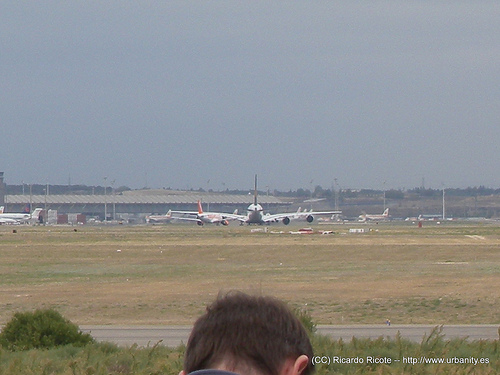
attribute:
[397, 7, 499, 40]
clouds — white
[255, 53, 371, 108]
clouds — white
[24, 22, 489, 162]
sky — blue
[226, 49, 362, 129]
sky — blue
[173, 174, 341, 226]
plane — white 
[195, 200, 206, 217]
tail — red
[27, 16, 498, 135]
clouds — white 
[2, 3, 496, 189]
sky — beautiful, blue, grey , overcast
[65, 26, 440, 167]
sky — overcast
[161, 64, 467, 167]
clouds — white 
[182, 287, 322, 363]
hair — brown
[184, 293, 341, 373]
hair — brown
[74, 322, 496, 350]
road — gray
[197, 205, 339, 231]
planes — distant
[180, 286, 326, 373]
hair — black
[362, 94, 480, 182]
clouds — white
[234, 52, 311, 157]
clouds — white